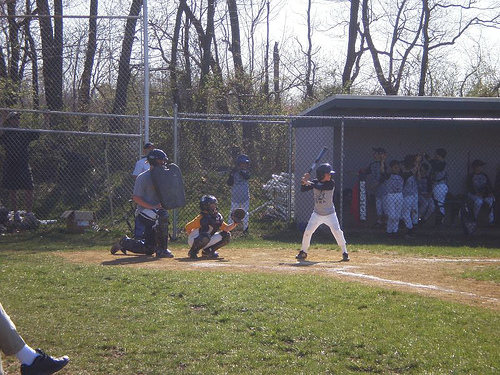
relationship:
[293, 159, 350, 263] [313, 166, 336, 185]
boy has head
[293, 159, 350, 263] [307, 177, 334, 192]
boy has arm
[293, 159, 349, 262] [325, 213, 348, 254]
boy has leg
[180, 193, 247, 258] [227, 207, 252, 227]
catcher has mitt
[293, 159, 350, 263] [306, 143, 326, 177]
boy holding bat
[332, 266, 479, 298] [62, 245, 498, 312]
line in dirt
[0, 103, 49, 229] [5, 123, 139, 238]
man leaning against fence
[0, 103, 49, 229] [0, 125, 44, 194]
man wearing clothes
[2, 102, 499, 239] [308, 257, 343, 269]
fence behind home plate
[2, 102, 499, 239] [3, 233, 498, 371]
fence around field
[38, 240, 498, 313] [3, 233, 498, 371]
dirt on field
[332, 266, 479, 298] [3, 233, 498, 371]
line on field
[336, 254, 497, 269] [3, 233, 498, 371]
line on field